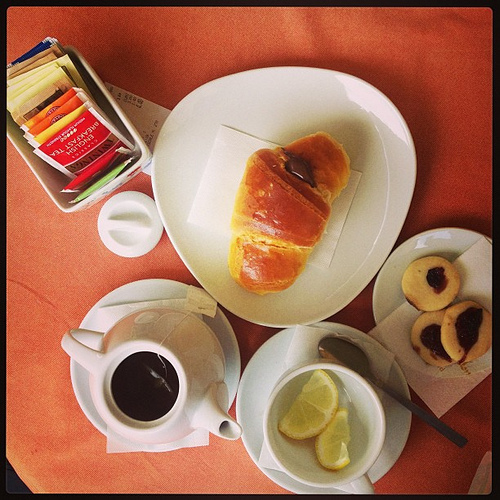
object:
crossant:
[226, 130, 351, 295]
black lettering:
[116, 91, 144, 108]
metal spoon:
[316, 333, 470, 450]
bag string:
[156, 297, 197, 379]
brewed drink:
[108, 349, 182, 424]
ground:
[3, 6, 493, 494]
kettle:
[61, 306, 243, 443]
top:
[96, 190, 163, 260]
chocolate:
[286, 156, 316, 189]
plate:
[151, 64, 420, 330]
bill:
[99, 78, 172, 177]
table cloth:
[427, 17, 476, 177]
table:
[7, 6, 493, 495]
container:
[4, 39, 151, 212]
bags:
[6, 34, 154, 213]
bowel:
[262, 362, 386, 490]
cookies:
[400, 254, 493, 371]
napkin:
[95, 296, 218, 453]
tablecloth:
[11, 220, 58, 439]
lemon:
[277, 368, 351, 470]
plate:
[371, 227, 491, 380]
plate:
[235, 322, 412, 494]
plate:
[69, 278, 240, 446]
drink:
[110, 350, 177, 422]